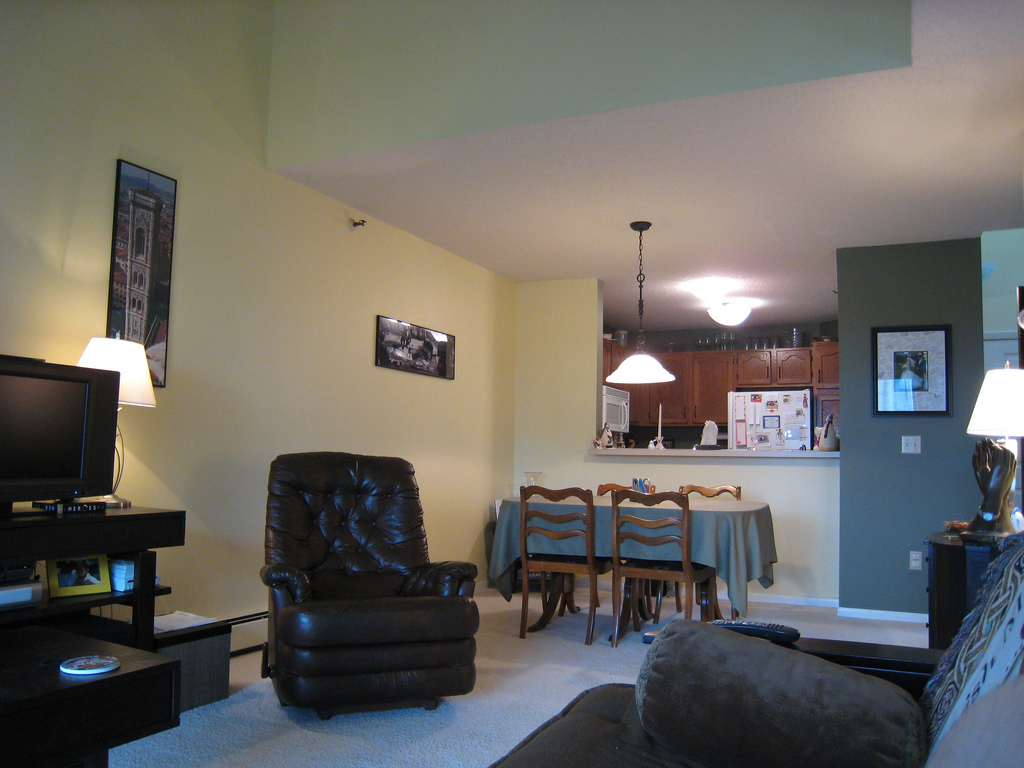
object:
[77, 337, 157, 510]
lamp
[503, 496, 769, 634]
table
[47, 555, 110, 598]
picture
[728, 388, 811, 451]
white fridge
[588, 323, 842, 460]
kitchen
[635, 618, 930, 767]
tube pillow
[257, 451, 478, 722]
recliner chair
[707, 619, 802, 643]
remote control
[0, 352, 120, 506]
flatscreen tv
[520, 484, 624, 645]
wooden chair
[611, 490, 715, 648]
wooden chair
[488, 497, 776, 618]
green tablecloth